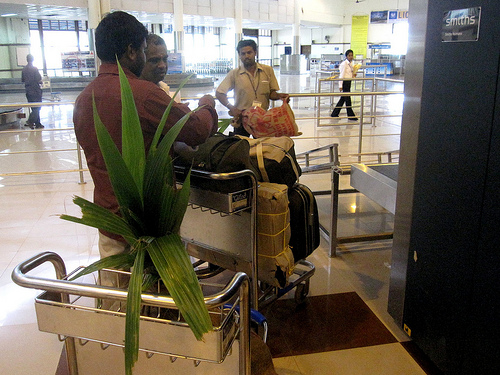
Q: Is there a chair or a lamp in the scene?
A: No, there are no chairs or lamps.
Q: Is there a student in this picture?
A: No, there are no students.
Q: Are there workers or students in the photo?
A: No, there are no students or workers.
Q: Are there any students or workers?
A: No, there are no students or workers.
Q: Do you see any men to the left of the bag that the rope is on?
A: Yes, there is a man to the left of the bag.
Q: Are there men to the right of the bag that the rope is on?
A: No, the man is to the left of the bag.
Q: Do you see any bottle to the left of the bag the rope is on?
A: No, there is a man to the left of the bag.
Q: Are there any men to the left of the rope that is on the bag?
A: Yes, there is a man to the left of the rope.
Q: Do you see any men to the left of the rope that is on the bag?
A: Yes, there is a man to the left of the rope.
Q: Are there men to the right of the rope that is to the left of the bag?
A: No, the man is to the left of the rope.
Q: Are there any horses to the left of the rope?
A: No, there is a man to the left of the rope.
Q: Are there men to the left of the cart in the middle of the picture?
A: Yes, there is a man to the left of the cart.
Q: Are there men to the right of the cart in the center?
A: No, the man is to the left of the cart.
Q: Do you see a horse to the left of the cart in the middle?
A: No, there is a man to the left of the cart.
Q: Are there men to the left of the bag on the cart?
A: Yes, there is a man to the left of the bag.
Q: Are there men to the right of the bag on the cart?
A: No, the man is to the left of the bag.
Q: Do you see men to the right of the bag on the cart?
A: No, the man is to the left of the bag.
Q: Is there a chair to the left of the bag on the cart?
A: No, there is a man to the left of the bag.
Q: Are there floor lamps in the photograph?
A: No, there are no floor lamps.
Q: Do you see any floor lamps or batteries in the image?
A: No, there are no floor lamps or batteries.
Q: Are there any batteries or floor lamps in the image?
A: No, there are no floor lamps or batteries.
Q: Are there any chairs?
A: No, there are no chairs.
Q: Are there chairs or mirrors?
A: No, there are no chairs or mirrors.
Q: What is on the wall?
A: The sign is on the wall.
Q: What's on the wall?
A: The sign is on the wall.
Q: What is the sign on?
A: The sign is on the wall.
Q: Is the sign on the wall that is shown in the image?
A: Yes, the sign is on the wall.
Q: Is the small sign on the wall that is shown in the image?
A: Yes, the sign is on the wall.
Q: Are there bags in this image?
A: Yes, there is a bag.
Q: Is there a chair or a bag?
A: Yes, there is a bag.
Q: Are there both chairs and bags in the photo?
A: No, there is a bag but no chairs.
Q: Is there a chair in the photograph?
A: No, there are no chairs.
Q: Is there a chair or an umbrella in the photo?
A: No, there are no chairs or umbrellas.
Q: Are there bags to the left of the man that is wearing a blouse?
A: Yes, there is a bag to the left of the man.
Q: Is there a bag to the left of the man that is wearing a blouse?
A: Yes, there is a bag to the left of the man.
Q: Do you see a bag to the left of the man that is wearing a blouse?
A: Yes, there is a bag to the left of the man.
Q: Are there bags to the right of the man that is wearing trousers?
A: No, the bag is to the left of the man.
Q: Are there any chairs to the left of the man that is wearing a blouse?
A: No, there is a bag to the left of the man.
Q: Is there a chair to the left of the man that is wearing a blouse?
A: No, there is a bag to the left of the man.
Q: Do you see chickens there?
A: No, there are no chickens.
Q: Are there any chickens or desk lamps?
A: No, there are no chickens or desk lamps.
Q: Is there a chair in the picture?
A: No, there are no chairs.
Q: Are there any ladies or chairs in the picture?
A: No, there are no chairs or ladies.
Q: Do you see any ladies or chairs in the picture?
A: No, there are no chairs or ladies.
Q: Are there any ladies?
A: No, there are no ladies.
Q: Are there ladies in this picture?
A: No, there are no ladies.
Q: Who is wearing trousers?
A: The man is wearing trousers.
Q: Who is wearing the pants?
A: The man is wearing trousers.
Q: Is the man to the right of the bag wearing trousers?
A: Yes, the man is wearing trousers.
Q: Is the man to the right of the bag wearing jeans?
A: No, the man is wearing trousers.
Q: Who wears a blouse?
A: The man wears a blouse.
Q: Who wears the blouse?
A: The man wears a blouse.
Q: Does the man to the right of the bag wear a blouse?
A: Yes, the man wears a blouse.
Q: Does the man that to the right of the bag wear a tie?
A: No, the man wears a blouse.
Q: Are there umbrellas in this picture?
A: No, there are no umbrellas.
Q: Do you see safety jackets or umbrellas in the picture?
A: No, there are no umbrellas or safety jackets.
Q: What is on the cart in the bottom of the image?
A: The plant is on the cart.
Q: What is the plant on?
A: The plant is on the cart.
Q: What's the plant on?
A: The plant is on the cart.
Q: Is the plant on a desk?
A: No, the plant is on the cart.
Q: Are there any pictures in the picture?
A: No, there are no pictures.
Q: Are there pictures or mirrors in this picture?
A: No, there are no pictures or mirrors.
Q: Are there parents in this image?
A: No, there are no parents.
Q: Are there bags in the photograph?
A: Yes, there is a bag.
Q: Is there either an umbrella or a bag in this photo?
A: Yes, there is a bag.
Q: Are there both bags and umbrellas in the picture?
A: No, there is a bag but no umbrellas.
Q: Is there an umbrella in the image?
A: No, there are no umbrellas.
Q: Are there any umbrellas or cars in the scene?
A: No, there are no umbrellas or cars.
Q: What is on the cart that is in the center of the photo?
A: The bag is on the cart.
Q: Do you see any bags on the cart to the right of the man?
A: Yes, there is a bag on the cart.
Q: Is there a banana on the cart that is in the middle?
A: No, there is a bag on the cart.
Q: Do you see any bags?
A: Yes, there is a bag.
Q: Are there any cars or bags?
A: Yes, there is a bag.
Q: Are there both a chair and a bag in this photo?
A: No, there is a bag but no chairs.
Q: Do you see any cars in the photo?
A: No, there are no cars.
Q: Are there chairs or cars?
A: No, there are no cars or chairs.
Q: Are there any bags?
A: Yes, there is a bag.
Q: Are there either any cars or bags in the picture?
A: Yes, there is a bag.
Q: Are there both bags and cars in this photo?
A: No, there is a bag but no cars.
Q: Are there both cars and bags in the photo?
A: No, there is a bag but no cars.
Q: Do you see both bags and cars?
A: No, there is a bag but no cars.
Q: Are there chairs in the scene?
A: No, there are no chairs.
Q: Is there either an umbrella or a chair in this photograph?
A: No, there are no chairs or umbrellas.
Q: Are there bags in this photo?
A: Yes, there is a bag.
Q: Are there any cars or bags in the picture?
A: Yes, there is a bag.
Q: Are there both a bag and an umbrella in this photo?
A: No, there is a bag but no umbrellas.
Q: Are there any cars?
A: No, there are no cars.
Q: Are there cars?
A: No, there are no cars.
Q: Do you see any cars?
A: No, there are no cars.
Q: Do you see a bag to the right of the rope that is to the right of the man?
A: Yes, there is a bag to the right of the rope.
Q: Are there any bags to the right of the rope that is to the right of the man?
A: Yes, there is a bag to the right of the rope.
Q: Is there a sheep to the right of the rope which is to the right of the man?
A: No, there is a bag to the right of the rope.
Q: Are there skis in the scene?
A: No, there are no skis.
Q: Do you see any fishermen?
A: No, there are no fishermen.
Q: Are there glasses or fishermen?
A: No, there are no fishermen or glasses.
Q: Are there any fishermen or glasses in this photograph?
A: No, there are no fishermen or glasses.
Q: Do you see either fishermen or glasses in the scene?
A: No, there are no fishermen or glasses.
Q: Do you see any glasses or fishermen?
A: No, there are no fishermen or glasses.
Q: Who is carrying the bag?
A: The man is carrying the bag.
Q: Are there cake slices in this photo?
A: No, there are no cake slices.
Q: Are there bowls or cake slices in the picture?
A: No, there are no cake slices or bowls.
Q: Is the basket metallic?
A: Yes, the basket is metallic.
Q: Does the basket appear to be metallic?
A: Yes, the basket is metallic.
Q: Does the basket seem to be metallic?
A: Yes, the basket is metallic.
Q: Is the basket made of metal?
A: Yes, the basket is made of metal.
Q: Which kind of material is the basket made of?
A: The basket is made of metal.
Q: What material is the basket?
A: The basket is made of metal.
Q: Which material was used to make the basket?
A: The basket is made of metal.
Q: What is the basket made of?
A: The basket is made of metal.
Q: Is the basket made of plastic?
A: No, the basket is made of metal.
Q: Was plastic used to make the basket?
A: No, the basket is made of metal.